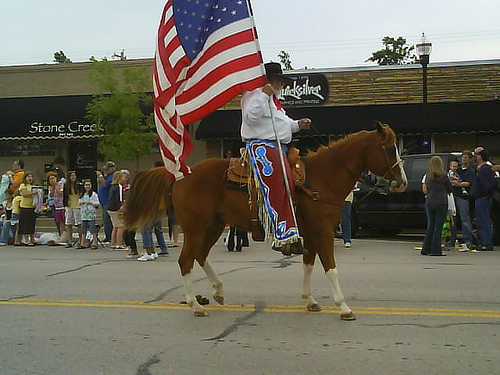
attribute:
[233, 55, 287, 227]
man — cowboy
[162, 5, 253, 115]
flag — american, large, red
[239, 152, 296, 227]
pants — dark, blue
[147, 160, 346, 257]
horse — brown, walking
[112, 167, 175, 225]
tail — brown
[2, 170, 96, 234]
audience — standing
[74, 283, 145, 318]
lines — yellow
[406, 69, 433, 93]
light — black, off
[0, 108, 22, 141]
awning — black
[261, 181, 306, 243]
chaps — red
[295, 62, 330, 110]
sign — black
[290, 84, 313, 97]
lettering — white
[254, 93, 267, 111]
shirt — white, yellow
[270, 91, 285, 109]
tie — red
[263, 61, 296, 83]
hat — cowboy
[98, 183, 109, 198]
jacket — blue